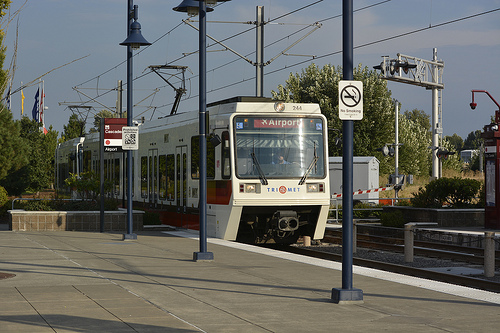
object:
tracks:
[322, 215, 460, 290]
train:
[107, 92, 371, 257]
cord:
[57, 3, 360, 110]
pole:
[333, 2, 363, 307]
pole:
[117, 1, 152, 240]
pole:
[413, 38, 453, 193]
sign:
[97, 117, 142, 154]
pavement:
[2, 228, 498, 330]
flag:
[31, 97, 39, 119]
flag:
[38, 92, 45, 118]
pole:
[39, 117, 49, 132]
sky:
[4, 3, 497, 97]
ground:
[395, 174, 422, 216]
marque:
[253, 116, 304, 128]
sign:
[337, 79, 365, 120]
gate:
[329, 176, 399, 202]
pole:
[194, 11, 214, 266]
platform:
[26, 219, 495, 327]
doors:
[185, 133, 207, 208]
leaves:
[9, 131, 57, 198]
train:
[30, 91, 341, 238]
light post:
[371, 46, 455, 186]